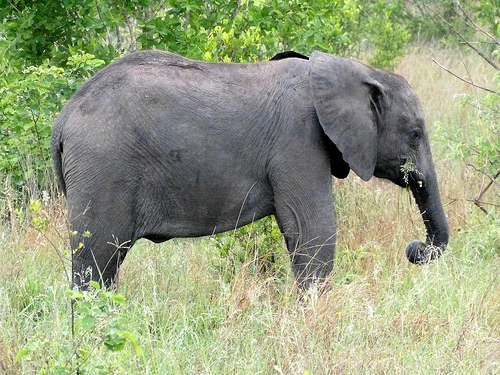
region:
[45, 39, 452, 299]
an elephant in the wild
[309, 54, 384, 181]
an ear of an elephant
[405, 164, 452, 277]
a trunk of an elephant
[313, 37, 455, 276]
an elephant eating leaves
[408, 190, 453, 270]
the trunk of an elephant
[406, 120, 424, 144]
an eye of an elephant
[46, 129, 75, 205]
the tail of an elephant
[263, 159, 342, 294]
the front leg of an elephant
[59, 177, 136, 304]
the hind leg of an elephant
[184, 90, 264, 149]
the skin of an elephant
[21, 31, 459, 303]
a grey elephant standing in a field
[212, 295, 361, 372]
long yellow grass growing in the field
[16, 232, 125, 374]
a small plant growing in the field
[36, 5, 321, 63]
green leaves of the trees behind the elephant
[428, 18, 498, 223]
several branches barren of leaves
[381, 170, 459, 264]
grey trunk of the elephant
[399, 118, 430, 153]
black eye of the elephant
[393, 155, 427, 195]
leafy plant in the elephants mouth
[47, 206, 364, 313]
grey legs of the elephant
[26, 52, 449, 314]
a grey elephant facing to the right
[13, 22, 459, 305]
grey elephant grazing alone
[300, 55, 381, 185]
elephants right ear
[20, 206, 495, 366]
tall mixed grass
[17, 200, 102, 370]
small tree growing through grass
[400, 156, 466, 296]
elephants slightly curled trunk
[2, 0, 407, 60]
green trees beside elephant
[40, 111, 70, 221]
elephants tail against body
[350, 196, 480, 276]
patches of dead grass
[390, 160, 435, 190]
elephant with grass in mouth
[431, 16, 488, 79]
bare dead tree branches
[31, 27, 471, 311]
a grey elephant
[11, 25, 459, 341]
an elephant in the grass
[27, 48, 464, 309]
the elephant has rough skin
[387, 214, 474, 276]
the end of the elephant's trunk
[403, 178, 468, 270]
the end of the trunk is curled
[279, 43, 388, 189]
the elephant's ear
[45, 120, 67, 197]
the elephant's tail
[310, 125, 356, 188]
shadow of the elephant's other ear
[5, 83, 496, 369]
some of the grass is dry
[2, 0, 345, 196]
bushes and trees in the background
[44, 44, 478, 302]
large gray elephant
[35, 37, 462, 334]
elephant standing in the grass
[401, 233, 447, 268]
bottom of the trunk is curled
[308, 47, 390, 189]
large gray ear on the side of the head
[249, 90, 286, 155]
lines on the skin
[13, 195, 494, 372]
tall grass on the ground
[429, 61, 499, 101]
branch with no leaves on it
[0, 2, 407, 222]
a plethora of bright green leaves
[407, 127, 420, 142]
eye on the side of the head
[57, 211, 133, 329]
hind leg in the grass